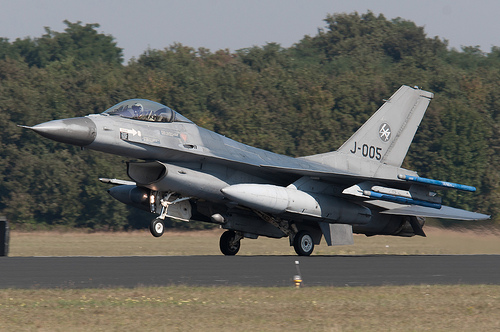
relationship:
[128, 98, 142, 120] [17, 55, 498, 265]
pilot of jet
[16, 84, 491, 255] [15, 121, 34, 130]
aircraft has nose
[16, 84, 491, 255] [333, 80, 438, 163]
aircraft has tail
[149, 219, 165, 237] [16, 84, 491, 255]
wheel on aircraft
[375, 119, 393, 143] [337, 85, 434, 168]
logo on tail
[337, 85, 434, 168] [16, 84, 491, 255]
tail on aircraft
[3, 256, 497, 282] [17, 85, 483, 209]
landing gear below jet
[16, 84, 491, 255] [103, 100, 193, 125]
aircraft has cockpit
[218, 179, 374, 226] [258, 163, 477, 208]
missile beneath wing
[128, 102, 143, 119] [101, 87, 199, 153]
pilot sitting in cockpit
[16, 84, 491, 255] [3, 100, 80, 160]
aircraft has nose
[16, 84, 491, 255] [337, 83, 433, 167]
aircraft has tail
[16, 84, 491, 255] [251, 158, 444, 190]
aircraft has wing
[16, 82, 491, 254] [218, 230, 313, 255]
aircraft has landing gear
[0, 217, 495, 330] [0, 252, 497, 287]
airfield has runway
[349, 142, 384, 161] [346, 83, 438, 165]
j-005 on tail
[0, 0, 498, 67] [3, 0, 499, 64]
cloud in sky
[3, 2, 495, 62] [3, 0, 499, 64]
cloud in sky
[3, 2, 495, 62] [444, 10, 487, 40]
cloud in sky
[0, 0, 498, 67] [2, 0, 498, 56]
cloud in sky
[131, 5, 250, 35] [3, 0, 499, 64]
clouds in sky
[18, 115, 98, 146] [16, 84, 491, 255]
nose of a aircraft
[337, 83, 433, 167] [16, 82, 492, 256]
tail of a plane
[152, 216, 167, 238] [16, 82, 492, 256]
wheel of a plane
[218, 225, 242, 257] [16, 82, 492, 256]
wheel of a plane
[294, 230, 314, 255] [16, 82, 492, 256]
tire of a plane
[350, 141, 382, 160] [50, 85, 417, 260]
j-005 of a jet plane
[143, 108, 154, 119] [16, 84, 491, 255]
chair of a aircraft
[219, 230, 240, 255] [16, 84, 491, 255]
wheel on aircraft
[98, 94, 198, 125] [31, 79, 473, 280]
cockpit of plane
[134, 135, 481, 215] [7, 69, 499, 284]
wing of plane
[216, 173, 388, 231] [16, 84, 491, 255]
turbine of aircraft